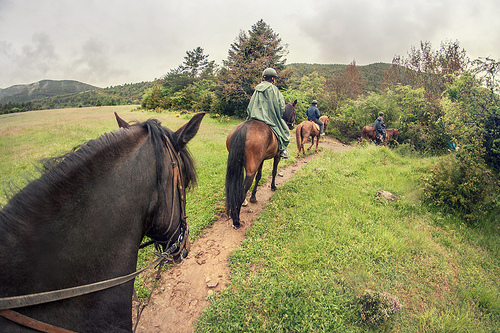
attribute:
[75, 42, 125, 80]
clouds — white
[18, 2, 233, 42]
sky — blue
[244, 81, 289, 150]
jacket — green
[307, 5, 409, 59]
clouds — white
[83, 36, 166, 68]
sky — blue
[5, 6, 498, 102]
sky — blue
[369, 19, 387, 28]
clouds — white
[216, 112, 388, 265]
horse — brown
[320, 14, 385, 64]
sky — blue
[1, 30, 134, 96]
cloud — white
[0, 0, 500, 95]
sky — blue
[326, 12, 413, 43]
clouds — white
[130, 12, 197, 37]
sky — blue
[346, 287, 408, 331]
pink flowers — small